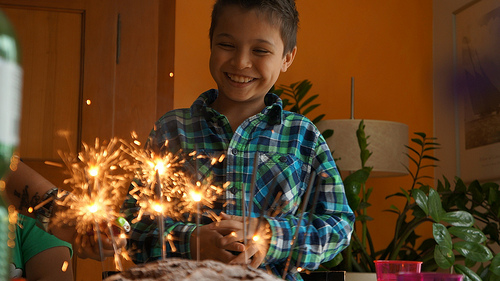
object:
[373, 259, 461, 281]
cup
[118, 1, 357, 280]
boy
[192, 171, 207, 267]
sparkler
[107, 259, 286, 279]
cake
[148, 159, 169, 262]
sparkler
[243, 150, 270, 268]
sparkler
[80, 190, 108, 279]
sparkler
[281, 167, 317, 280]
sparkler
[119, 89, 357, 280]
shirt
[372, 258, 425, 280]
drinking cup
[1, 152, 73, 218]
arm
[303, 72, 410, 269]
lamp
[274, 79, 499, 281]
house plant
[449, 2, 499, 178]
artwork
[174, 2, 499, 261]
wall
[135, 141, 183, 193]
glowing lights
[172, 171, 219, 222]
glowing lights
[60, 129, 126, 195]
glowing lights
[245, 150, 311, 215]
pocket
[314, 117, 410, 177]
shade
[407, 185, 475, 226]
leaf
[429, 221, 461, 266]
leaf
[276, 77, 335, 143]
leaf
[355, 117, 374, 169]
leaf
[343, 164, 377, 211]
leaf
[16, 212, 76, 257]
sleeve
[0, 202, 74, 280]
shirt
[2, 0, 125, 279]
door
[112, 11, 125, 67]
hinge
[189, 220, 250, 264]
hands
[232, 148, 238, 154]
button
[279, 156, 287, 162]
button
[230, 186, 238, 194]
button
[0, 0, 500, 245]
background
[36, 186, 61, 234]
watch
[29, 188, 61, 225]
woman's wrist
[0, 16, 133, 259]
person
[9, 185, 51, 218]
tatoo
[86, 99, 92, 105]
spark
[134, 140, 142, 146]
spark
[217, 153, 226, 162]
spark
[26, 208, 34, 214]
spark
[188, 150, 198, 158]
spark